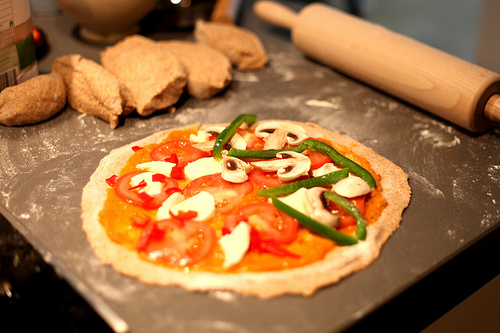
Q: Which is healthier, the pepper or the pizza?
A: The pepper is healthier than the pizza.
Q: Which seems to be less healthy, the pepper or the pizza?
A: The pizza is less healthy than the pepper.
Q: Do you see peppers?
A: Yes, there is a pepper.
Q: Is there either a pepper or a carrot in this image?
A: Yes, there is a pepper.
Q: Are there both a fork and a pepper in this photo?
A: No, there is a pepper but no forks.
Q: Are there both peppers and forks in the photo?
A: No, there is a pepper but no forks.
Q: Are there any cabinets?
A: No, there are no cabinets.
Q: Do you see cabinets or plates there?
A: No, there are no cabinets or plates.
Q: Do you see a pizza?
A: Yes, there is a pizza.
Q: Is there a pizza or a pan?
A: Yes, there is a pizza.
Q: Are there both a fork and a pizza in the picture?
A: No, there is a pizza but no forks.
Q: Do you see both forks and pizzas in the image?
A: No, there is a pizza but no forks.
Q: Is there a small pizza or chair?
A: Yes, there is a small pizza.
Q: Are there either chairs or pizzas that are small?
A: Yes, the pizza is small.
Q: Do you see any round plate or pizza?
A: Yes, there is a round pizza.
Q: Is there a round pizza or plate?
A: Yes, there is a round pizza.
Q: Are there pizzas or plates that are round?
A: Yes, the pizza is round.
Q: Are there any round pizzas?
A: Yes, there is a round pizza.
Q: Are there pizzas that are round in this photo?
A: Yes, there is a round pizza.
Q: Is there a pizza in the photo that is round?
A: Yes, there is a pizza that is round.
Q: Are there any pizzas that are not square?
A: Yes, there is a round pizza.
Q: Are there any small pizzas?
A: Yes, there is a small pizza.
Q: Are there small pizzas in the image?
A: Yes, there is a small pizza.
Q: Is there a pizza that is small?
A: Yes, there is a pizza that is small.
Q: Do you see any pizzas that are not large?
A: Yes, there is a small pizza.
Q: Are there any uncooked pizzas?
A: Yes, there is an uncooked pizza.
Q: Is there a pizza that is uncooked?
A: Yes, there is a pizza that is uncooked.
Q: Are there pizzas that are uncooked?
A: Yes, there is a pizza that is uncooked.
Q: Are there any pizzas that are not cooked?
A: Yes, there is a uncooked pizza.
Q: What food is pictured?
A: The food is a pizza.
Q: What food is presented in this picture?
A: The food is a pizza.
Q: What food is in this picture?
A: The food is a pizza.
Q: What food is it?
A: The food is a pizza.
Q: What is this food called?
A: This is a pizza.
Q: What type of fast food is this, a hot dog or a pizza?
A: This is a pizza.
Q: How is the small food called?
A: The food is a pizza.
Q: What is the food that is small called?
A: The food is a pizza.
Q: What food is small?
A: The food is a pizza.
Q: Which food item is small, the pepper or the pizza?
A: The pizza is small.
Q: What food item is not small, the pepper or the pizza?
A: The pepper is not small.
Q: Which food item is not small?
A: The food item is a pepper.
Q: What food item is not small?
A: The food item is a pepper.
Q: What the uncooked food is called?
A: The food is a pizza.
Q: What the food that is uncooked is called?
A: The food is a pizza.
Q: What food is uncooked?
A: The food is a pizza.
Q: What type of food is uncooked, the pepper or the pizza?
A: The pizza is uncooked.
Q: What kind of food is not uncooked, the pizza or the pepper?
A: The pepper is not uncooked.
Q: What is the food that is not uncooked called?
A: The food is a pepper.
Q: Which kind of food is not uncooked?
A: The food is a pepper.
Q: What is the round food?
A: The food is a pizza.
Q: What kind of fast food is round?
A: The fast food is a pizza.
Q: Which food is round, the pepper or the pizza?
A: The pizza is round.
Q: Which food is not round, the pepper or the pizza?
A: The pepper is not round.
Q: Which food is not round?
A: The food is a pepper.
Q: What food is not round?
A: The food is a pepper.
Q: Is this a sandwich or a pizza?
A: This is a pizza.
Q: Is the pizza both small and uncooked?
A: Yes, the pizza is small and uncooked.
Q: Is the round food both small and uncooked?
A: Yes, the pizza is small and uncooked.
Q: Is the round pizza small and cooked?
A: No, the pizza is small but uncooked.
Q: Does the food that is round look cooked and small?
A: No, the pizza is small but uncooked.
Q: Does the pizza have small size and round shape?
A: Yes, the pizza is small and round.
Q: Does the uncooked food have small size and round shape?
A: Yes, the pizza is small and round.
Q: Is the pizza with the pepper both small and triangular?
A: No, the pizza is small but round.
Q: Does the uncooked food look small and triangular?
A: No, the pizza is small but round.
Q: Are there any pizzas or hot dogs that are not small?
A: No, there is a pizza but it is small.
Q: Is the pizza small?
A: Yes, the pizza is small.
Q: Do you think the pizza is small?
A: Yes, the pizza is small.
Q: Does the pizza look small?
A: Yes, the pizza is small.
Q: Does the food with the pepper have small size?
A: Yes, the pizza is small.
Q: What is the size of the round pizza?
A: The pizza is small.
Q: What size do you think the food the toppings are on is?
A: The pizza is small.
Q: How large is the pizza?
A: The pizza is small.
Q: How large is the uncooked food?
A: The pizza is small.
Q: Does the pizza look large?
A: No, the pizza is small.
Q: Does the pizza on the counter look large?
A: No, the pizza is small.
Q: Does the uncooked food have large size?
A: No, the pizza is small.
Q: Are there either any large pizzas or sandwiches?
A: No, there is a pizza but it is small.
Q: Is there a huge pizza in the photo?
A: No, there is a pizza but it is small.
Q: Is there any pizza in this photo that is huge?
A: No, there is a pizza but it is small.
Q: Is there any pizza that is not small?
A: No, there is a pizza but it is small.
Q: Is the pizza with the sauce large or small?
A: The pizza is small.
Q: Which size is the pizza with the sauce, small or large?
A: The pizza is small.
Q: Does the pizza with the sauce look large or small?
A: The pizza is small.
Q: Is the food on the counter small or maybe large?
A: The pizza is small.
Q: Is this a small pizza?
A: Yes, this is a small pizza.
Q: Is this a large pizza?
A: No, this is a small pizza.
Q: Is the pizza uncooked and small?
A: Yes, the pizza is uncooked and small.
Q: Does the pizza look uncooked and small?
A: Yes, the pizza is uncooked and small.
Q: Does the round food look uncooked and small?
A: Yes, the pizza is uncooked and small.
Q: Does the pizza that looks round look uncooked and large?
A: No, the pizza is uncooked but small.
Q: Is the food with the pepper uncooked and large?
A: No, the pizza is uncooked but small.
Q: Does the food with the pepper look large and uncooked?
A: No, the pizza is uncooked but small.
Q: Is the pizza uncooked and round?
A: Yes, the pizza is uncooked and round.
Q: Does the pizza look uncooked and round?
A: Yes, the pizza is uncooked and round.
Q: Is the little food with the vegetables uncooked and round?
A: Yes, the pizza is uncooked and round.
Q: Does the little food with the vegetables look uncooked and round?
A: Yes, the pizza is uncooked and round.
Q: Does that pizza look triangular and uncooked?
A: No, the pizza is uncooked but round.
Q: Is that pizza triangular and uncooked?
A: No, the pizza is uncooked but round.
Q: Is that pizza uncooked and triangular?
A: No, the pizza is uncooked but round.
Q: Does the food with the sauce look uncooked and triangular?
A: No, the pizza is uncooked but round.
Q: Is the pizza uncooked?
A: Yes, the pizza is uncooked.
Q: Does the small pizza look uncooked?
A: Yes, the pizza is uncooked.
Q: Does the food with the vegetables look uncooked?
A: Yes, the pizza is uncooked.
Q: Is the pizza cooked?
A: No, the pizza is uncooked.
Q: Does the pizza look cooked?
A: No, the pizza is uncooked.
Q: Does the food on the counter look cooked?
A: No, the pizza is uncooked.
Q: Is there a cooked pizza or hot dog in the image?
A: No, there is a pizza but it is uncooked.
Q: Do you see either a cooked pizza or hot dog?
A: No, there is a pizza but it is uncooked.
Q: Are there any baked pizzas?
A: No, there is a pizza but it is uncooked.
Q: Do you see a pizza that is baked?
A: No, there is a pizza but it is uncooked.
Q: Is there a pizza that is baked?
A: No, there is a pizza but it is uncooked.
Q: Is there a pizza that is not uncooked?
A: No, there is a pizza but it is uncooked.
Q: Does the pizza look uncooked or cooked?
A: The pizza is uncooked.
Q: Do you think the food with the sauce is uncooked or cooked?
A: The pizza is uncooked.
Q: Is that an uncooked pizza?
A: Yes, that is an uncooked pizza.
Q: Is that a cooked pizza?
A: No, that is an uncooked pizza.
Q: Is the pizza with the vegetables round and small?
A: Yes, the pizza is round and small.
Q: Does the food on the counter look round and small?
A: Yes, the pizza is round and small.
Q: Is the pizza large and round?
A: No, the pizza is round but small.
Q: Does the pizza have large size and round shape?
A: No, the pizza is round but small.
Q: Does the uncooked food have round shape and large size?
A: No, the pizza is round but small.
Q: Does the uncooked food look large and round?
A: No, the pizza is round but small.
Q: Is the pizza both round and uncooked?
A: Yes, the pizza is round and uncooked.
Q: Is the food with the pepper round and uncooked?
A: Yes, the pizza is round and uncooked.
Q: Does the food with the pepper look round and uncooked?
A: Yes, the pizza is round and uncooked.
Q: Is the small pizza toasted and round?
A: No, the pizza is round but uncooked.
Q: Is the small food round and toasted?
A: No, the pizza is round but uncooked.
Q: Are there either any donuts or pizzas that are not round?
A: No, there is a pizza but it is round.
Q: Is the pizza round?
A: Yes, the pizza is round.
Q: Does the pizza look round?
A: Yes, the pizza is round.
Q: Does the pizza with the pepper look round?
A: Yes, the pizza is round.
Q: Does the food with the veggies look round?
A: Yes, the pizza is round.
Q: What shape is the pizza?
A: The pizza is round.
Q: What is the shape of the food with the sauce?
A: The pizza is round.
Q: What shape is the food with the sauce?
A: The pizza is round.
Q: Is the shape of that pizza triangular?
A: No, the pizza is round.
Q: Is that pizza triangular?
A: No, the pizza is round.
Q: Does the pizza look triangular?
A: No, the pizza is round.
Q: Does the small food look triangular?
A: No, the pizza is round.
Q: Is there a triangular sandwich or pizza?
A: No, there is a pizza but it is round.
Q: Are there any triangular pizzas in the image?
A: No, there is a pizza but it is round.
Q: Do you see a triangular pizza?
A: No, there is a pizza but it is round.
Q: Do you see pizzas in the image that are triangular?
A: No, there is a pizza but it is round.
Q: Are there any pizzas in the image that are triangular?
A: No, there is a pizza but it is round.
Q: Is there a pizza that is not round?
A: No, there is a pizza but it is round.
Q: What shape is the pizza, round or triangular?
A: The pizza is round.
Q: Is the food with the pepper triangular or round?
A: The pizza is round.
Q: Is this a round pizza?
A: Yes, this is a round pizza.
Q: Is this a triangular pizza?
A: No, this is a round pizza.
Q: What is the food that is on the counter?
A: The food is a pizza.